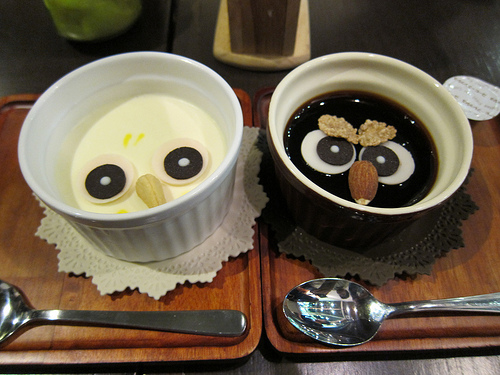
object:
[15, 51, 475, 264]
two cups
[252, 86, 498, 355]
plate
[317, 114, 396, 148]
flake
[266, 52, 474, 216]
bowl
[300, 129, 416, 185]
eyes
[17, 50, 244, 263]
bowl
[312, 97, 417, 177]
soup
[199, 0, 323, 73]
ground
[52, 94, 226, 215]
cream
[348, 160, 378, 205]
almond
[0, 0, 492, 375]
table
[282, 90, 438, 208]
chocolate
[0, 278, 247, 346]
spoon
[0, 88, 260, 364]
plates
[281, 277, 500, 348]
silver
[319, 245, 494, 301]
wooden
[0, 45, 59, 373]
left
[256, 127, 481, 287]
cloth